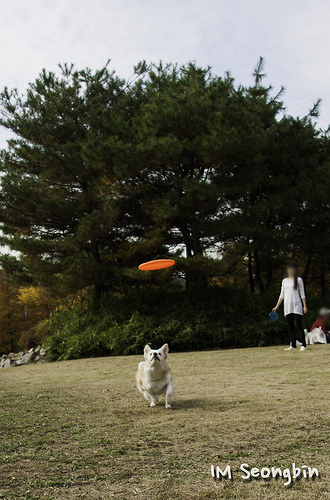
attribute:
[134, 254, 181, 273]
frisbee — orange, red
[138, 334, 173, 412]
dog — running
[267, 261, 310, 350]
woman — standing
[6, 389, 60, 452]
grass — brown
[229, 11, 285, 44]
sky — blue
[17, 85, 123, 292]
tree — green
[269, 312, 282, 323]
frisbee — blue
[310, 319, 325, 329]
blanket — red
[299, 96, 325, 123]
branches — green